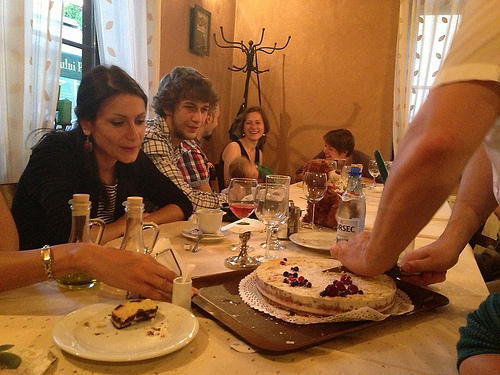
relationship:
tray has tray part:
[191, 270, 450, 352] [191, 266, 377, 353]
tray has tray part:
[191, 270, 450, 352] [395, 278, 449, 314]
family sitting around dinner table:
[1, 67, 385, 304] [1, 174, 492, 374]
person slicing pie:
[332, 1, 500, 285] [257, 258, 397, 318]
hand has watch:
[2, 243, 198, 300] [42, 244, 55, 280]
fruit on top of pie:
[283, 267, 310, 288] [257, 258, 397, 318]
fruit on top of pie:
[320, 277, 363, 296] [257, 258, 397, 318]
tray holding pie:
[191, 270, 450, 352] [257, 258, 397, 318]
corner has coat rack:
[163, 3, 296, 182] [213, 27, 291, 142]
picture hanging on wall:
[189, 6, 212, 56] [161, 3, 392, 167]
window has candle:
[1, 1, 160, 183] [57, 100, 71, 127]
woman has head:
[12, 67, 194, 244] [78, 67, 147, 163]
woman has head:
[222, 108, 267, 185] [243, 107, 266, 141]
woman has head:
[314, 130, 376, 179] [323, 129, 355, 159]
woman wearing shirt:
[12, 67, 194, 244] [12, 127, 193, 251]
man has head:
[143, 66, 227, 209] [154, 66, 210, 139]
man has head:
[178, 91, 221, 192] [204, 94, 220, 137]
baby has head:
[229, 157, 274, 179] [230, 157, 260, 179]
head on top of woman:
[78, 67, 147, 163] [12, 67, 194, 244]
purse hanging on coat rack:
[230, 45, 262, 140] [213, 27, 291, 142]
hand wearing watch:
[2, 243, 198, 300] [42, 244, 55, 280]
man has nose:
[143, 66, 227, 209] [194, 107, 202, 123]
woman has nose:
[12, 67, 194, 244] [126, 119, 138, 138]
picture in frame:
[189, 6, 212, 56] [188, 3, 213, 56]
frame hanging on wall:
[188, 3, 213, 56] [161, 3, 392, 167]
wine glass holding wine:
[229, 179, 257, 250] [229, 203, 256, 220]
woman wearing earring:
[12, 67, 194, 244] [83, 134, 93, 150]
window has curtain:
[1, 1, 160, 183] [1, 1, 63, 183]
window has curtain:
[1, 1, 160, 183] [94, 1, 159, 118]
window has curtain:
[407, 7, 461, 125] [393, 3, 466, 154]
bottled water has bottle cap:
[338, 168, 365, 241] [349, 166, 362, 178]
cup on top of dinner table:
[189, 209, 222, 235] [1, 174, 492, 374]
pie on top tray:
[257, 258, 397, 318] [191, 270, 450, 352]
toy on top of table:
[303, 159, 342, 228] [1, 174, 492, 374]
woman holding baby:
[222, 108, 267, 185] [229, 157, 274, 179]